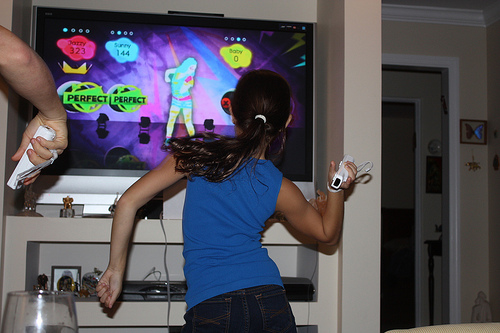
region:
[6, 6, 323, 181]
a television with a video game on screen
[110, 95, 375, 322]
young girl playing a video game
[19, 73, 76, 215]
a game controller for video game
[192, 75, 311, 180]
girl with her hair in a pony tail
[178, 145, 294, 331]
girl wearing a blue tank top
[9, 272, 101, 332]
glass sitting on table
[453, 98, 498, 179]
picture of butterfly hanging on wall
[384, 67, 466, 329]
door way leading to another room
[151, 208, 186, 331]
wires hanging down from video game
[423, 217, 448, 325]
small console table in the hall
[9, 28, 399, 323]
two people are playing a game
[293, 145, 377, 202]
the girl is holding a controller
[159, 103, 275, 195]
the girls hair is in a ponytial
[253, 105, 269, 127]
the girls pony tail holder is white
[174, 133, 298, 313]
the girls t-shirt is blue in color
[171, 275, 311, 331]
the girl is wearing jeans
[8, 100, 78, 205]
this person is holding a controller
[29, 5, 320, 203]
The television displays the video game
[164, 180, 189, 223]
a portion of the gaming console is visible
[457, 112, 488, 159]
a picture of a butterfly hangs on the wall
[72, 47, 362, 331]
a girl playing the wii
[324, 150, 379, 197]
her right hand is holding the control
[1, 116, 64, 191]
a large hand holding a remote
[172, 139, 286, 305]
she is wearing a blue shirt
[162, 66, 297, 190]
her hair is in a ponytail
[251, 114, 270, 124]
the ponytail holder is white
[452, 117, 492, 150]
a blue butterfly in a frame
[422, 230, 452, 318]
a table through the doorway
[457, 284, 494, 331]
a white statue on the floor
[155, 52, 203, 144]
an avatar on the screen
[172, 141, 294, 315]
Blue sleeveless shirt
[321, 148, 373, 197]
Wii controller held by girl with blue shirt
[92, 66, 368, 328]
Girl wearing blue sleeveless shirt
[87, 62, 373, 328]
Girl with black hair in ponytail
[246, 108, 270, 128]
White ponytail holder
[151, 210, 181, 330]
Gray wire hanging down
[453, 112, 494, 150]
Picture hanging on wall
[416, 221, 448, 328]
Small table between doorways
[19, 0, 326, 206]
Flat-screen TV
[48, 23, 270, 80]
Scores of a game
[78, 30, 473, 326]
A person is playing a video game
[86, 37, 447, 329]
The person is having some fun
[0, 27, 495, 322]
A person is playing with a friend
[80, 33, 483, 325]
A person is holding a game controller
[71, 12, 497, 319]
A person is facing a TV screen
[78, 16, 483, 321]
A person is in somebody's house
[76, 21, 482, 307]
A person is inside a room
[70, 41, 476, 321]
A person is enjoying recreation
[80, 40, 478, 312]
A person is wearing a blue shirt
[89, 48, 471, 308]
A person has dark colored hair